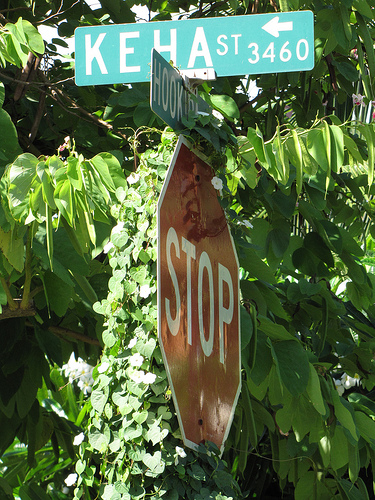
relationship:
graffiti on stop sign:
[179, 173, 229, 246] [153, 133, 243, 461]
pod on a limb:
[287, 129, 306, 197] [226, 112, 361, 168]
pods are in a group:
[57, 137, 127, 223] [4, 142, 128, 319]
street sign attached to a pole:
[73, 7, 315, 86] [128, 126, 189, 500]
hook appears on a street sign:
[154, 61, 186, 127] [147, 50, 228, 172]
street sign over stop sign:
[73, 7, 315, 86] [153, 133, 243, 461]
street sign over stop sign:
[147, 50, 228, 172] [153, 133, 243, 461]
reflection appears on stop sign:
[167, 243, 229, 428] [153, 133, 243, 461]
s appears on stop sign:
[164, 225, 183, 340] [153, 133, 243, 461]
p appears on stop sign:
[216, 260, 237, 369] [153, 133, 243, 461]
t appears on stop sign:
[180, 235, 199, 353] [153, 133, 243, 461]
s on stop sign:
[164, 225, 183, 340] [153, 133, 243, 461]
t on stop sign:
[180, 235, 199, 353] [153, 133, 243, 461]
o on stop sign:
[196, 250, 215, 357] [153, 133, 243, 461]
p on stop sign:
[216, 260, 237, 369] [153, 133, 243, 461]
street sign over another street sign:
[73, 7, 315, 86] [147, 50, 228, 172]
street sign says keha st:
[73, 7, 315, 86] [84, 29, 243, 76]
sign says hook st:
[147, 50, 228, 172] [154, 61, 186, 127]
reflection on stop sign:
[167, 243, 229, 428] [153, 133, 243, 461]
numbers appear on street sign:
[244, 39, 309, 64] [73, 7, 315, 86]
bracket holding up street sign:
[174, 68, 216, 82] [73, 7, 315, 86]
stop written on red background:
[165, 222, 236, 368] [161, 144, 238, 448]